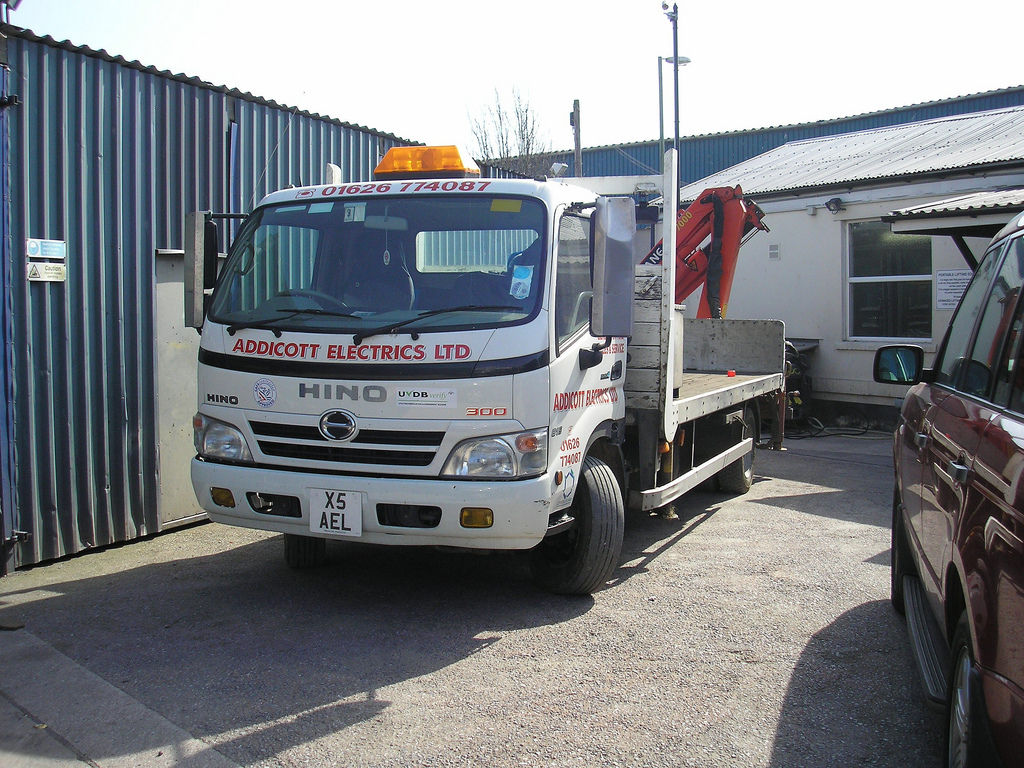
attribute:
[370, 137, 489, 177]
light — yellow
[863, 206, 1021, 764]
truck — maroon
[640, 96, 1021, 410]
building — white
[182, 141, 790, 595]
truck — white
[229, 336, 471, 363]
text — red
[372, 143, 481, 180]
light — orange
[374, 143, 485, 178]
light — orange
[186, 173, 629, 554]
truck cab — white